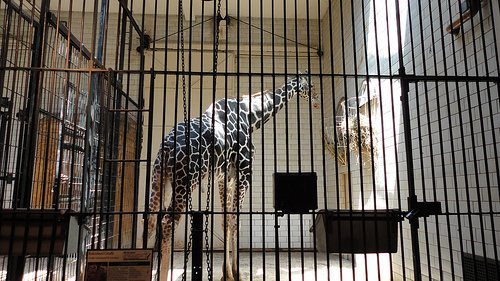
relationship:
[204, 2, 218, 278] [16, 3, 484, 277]
chain inside cage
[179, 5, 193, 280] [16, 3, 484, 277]
chain inside cage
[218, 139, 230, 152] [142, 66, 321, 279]
spot adorning giraffe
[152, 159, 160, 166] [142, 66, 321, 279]
spot adorning giraffe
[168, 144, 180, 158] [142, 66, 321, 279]
spot adorning giraffe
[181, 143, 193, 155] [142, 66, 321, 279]
spot adorning giraffe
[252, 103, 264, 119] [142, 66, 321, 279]
spot adorning giraffe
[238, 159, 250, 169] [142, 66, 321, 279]
spot adorning giraffe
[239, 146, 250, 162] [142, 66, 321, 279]
spot adorning giraffe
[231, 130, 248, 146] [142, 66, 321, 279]
spot adorning giraffe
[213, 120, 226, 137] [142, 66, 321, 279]
spot adorning giraffe